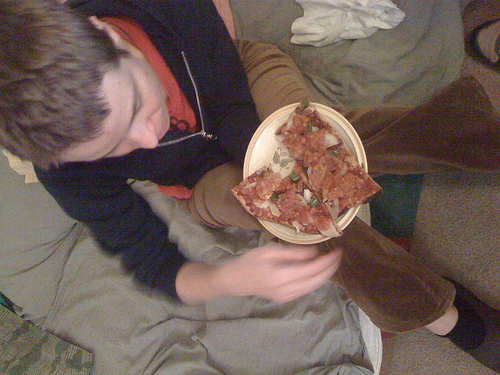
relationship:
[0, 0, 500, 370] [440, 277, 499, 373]
guy wearing loafer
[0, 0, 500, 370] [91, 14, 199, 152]
guy wearing shirt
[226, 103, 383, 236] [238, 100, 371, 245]
food on plate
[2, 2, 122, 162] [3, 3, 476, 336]
hair on man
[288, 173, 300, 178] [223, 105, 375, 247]
topping on plate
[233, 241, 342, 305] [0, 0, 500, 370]
hand of guy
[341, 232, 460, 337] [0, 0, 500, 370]
leg of guy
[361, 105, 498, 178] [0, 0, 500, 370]
leg of guy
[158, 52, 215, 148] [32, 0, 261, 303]
zipper on jacket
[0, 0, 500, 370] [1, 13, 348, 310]
guy wearing jacket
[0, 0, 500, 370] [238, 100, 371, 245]
guy holding plate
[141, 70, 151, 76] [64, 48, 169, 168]
pimple on face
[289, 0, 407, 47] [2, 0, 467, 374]
towel on couch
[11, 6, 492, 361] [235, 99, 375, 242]
guy eating food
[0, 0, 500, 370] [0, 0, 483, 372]
guy sitting on bed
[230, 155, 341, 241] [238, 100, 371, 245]
pizza on plate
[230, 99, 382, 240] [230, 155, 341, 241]
pizza on pizza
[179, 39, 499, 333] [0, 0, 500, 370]
pants on guy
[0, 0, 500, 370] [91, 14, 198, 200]
guy wearing shirt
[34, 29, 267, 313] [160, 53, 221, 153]
sweater has zip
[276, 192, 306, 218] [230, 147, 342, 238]
meat chunk on pizza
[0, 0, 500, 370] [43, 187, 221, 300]
guy has arm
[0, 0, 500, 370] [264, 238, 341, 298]
guy has fingers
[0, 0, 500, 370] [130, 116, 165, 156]
guy has nose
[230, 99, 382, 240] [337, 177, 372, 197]
pizza has sauce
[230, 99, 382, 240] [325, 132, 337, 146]
pizza has cheese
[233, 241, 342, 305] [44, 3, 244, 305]
hand with shirt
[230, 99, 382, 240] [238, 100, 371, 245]
pizza on plate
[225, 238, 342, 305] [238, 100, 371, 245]
hand near plate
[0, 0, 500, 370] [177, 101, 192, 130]
guy wears shirt